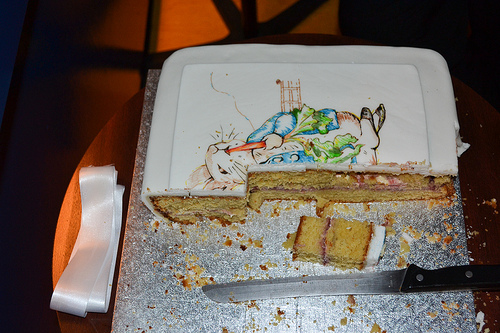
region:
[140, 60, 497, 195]
Cake with vanilla icing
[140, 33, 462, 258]
Cake with a rabbit on it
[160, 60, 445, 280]
Half of a cake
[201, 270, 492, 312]
large knife with a silve blade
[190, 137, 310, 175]
rabbit eaing a carrot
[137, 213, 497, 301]
cake crumbs on a cookie sheet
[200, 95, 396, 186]
Bunny rabbit with a blue coat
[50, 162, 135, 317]
folded white ribbon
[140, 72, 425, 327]
cake on a silver cookie sheet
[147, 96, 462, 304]
vanilla cake with pieces missing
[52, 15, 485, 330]
a half-eaten party cake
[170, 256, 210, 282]
crumbs on the serving tray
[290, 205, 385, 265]
small, uneaten piece of cake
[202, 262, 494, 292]
cutting knife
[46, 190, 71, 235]
edge of a round, wooden table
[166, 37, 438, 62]
frosted end of the cake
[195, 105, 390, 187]
drawing of a rabbit on the cake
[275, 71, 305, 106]
fence made of icing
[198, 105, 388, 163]
rabitt in a blue jacket eating a carrot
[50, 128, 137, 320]
White ribbon laying on a table.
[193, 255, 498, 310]
A long knife with a brown handle.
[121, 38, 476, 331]
A cake that has been partially eaten.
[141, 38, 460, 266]
What's left of a two layer cake.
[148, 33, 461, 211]
Cake with white icing.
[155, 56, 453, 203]
Part of a cake that has the picture of a rabbit on the top.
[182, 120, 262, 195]
A rabbit's head.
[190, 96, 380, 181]
A rabbit holding an orange carrot.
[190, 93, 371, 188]
A rabbit wearing a blue coat.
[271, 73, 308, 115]
A brown fence near the rabbit.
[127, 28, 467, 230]
birthday cake with Peter Rabbit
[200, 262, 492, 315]
serrated knife with black handle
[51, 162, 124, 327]
thick white ribbon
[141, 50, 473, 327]
half of a cake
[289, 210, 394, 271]
yellow cake with raspberry filling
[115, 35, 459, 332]
cake on a silver tray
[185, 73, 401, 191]
Peter Rabbit design in frosting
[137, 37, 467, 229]
cake with white frosting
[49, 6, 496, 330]
cake on a round table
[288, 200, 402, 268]
small slice of cake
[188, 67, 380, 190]
Bunny image on top of cake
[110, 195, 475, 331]
Silver foil tray on bottom of cake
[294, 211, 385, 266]
Slice of cake sitting on tray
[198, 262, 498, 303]
Long knife with black handle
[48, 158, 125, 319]
White ribbon sitting on table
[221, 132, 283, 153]
Carrot in rabbit's hand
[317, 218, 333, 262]
Filling in center of cake slice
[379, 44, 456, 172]
White frosting on top of cake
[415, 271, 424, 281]
Silver rivot on side of knife handle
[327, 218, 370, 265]
Soft yellow sponge cake